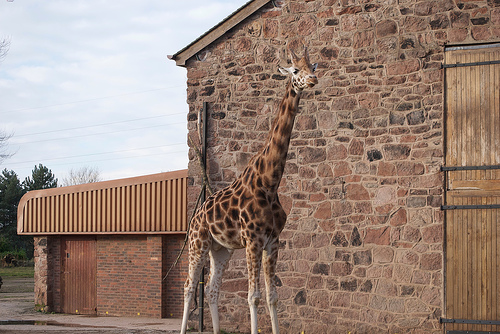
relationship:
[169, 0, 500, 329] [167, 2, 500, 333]
walls are made of stone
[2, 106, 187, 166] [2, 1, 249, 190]
electrical lines are in sky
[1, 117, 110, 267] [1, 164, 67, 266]
trees have leaves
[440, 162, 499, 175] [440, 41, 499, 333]
latch on door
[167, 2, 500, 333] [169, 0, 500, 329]
stone on wall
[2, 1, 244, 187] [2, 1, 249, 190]
clouds are in sky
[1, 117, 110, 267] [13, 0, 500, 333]
trees are on side of building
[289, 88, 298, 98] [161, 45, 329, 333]
spot on giraffe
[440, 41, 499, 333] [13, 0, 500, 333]
door on building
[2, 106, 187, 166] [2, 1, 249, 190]
electrical lines are against sky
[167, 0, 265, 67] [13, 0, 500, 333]
roof on top of building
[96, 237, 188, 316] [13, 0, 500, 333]
bricks on building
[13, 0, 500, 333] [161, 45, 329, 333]
building behind giraffe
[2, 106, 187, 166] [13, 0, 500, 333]
electrical lines are above building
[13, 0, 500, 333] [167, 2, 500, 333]
building made of stone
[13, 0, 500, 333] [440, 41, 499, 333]
building has a door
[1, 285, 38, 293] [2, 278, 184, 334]
dirt on ground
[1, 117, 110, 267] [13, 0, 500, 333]
trees are behind building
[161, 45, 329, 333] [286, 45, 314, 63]
giraffe has horns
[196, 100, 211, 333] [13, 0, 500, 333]
pole on side of building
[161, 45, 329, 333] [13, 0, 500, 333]
giraffe standing next to building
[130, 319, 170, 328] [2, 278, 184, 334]
water on ground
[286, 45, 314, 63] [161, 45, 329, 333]
horns on giraffe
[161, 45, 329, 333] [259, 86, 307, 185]
giraffe has a neck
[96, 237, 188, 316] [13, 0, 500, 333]
bricks are on building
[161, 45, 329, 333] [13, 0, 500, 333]
giraffe standing by a building